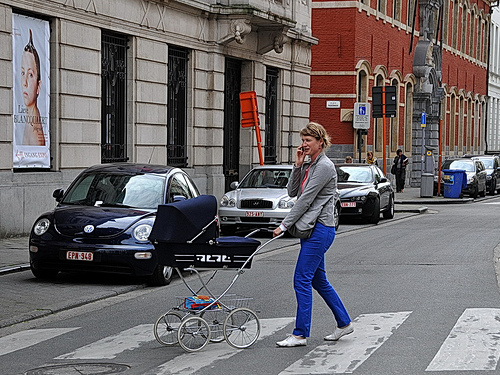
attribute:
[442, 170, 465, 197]
garbage can — blue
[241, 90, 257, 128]
street sign — orange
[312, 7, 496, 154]
building — brick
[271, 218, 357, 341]
pants — blue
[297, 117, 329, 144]
woman — blonde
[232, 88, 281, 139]
sign — red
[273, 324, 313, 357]
shoe — white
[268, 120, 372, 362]
lady wearing — blue and gray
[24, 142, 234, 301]
car — small, navy blue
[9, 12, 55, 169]
white sign — large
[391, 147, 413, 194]
person wearing — black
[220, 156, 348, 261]
silver car — parked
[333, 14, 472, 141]
red building — large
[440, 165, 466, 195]
trash can — blue